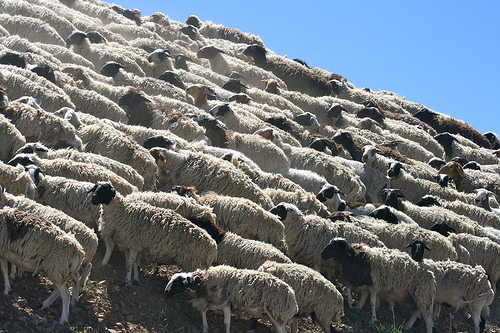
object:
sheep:
[315, 183, 417, 226]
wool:
[188, 263, 299, 326]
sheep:
[268, 202, 388, 285]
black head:
[433, 132, 461, 158]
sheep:
[432, 132, 500, 165]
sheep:
[240, 44, 331, 98]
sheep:
[85, 181, 218, 290]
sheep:
[360, 145, 441, 184]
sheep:
[415, 194, 500, 230]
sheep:
[147, 146, 275, 212]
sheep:
[52, 105, 157, 191]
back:
[14, 222, 86, 285]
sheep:
[0, 206, 86, 327]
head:
[162, 273, 194, 299]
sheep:
[206, 103, 302, 148]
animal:
[361, 141, 440, 181]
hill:
[23, 142, 468, 332]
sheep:
[320, 237, 437, 332]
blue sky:
[97, 0, 499, 140]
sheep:
[143, 136, 262, 184]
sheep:
[117, 89, 206, 143]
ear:
[201, 85, 217, 97]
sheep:
[182, 15, 263, 48]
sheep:
[406, 240, 494, 333]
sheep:
[324, 211, 457, 262]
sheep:
[183, 215, 293, 271]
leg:
[223, 303, 230, 332]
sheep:
[197, 118, 291, 175]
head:
[87, 180, 117, 207]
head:
[386, 161, 410, 178]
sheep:
[377, 189, 499, 244]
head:
[406, 240, 432, 262]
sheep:
[65, 29, 146, 77]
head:
[64, 30, 88, 48]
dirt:
[97, 286, 162, 318]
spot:
[99, 60, 194, 105]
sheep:
[251, 127, 366, 205]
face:
[315, 184, 347, 205]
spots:
[432, 131, 498, 164]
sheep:
[384, 161, 471, 204]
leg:
[367, 284, 378, 325]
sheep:
[172, 54, 230, 88]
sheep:
[163, 264, 299, 332]